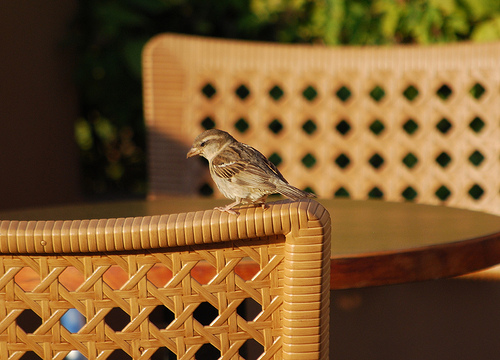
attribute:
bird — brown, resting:
[182, 116, 312, 221]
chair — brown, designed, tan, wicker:
[2, 198, 336, 353]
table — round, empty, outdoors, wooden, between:
[5, 190, 499, 295]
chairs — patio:
[12, 22, 499, 250]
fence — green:
[75, 117, 143, 193]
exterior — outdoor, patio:
[7, 5, 499, 360]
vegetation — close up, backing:
[80, 5, 499, 44]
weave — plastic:
[3, 206, 333, 270]